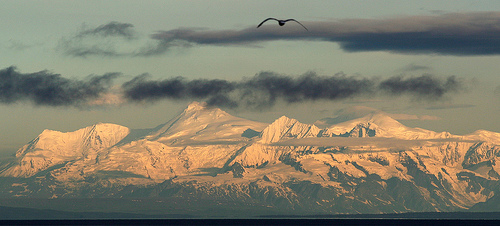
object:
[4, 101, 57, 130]
sky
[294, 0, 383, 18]
sky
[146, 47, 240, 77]
sky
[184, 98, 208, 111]
top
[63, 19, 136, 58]
cloud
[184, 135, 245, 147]
snow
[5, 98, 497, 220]
snow valley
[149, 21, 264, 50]
cloud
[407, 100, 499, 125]
sky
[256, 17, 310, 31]
bird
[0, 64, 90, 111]
black clouds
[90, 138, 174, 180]
moutain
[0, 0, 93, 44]
sky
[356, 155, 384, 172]
snow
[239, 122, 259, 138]
shadow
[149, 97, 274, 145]
mountain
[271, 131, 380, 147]
snow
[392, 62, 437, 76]
clouds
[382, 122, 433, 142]
snow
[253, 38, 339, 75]
sky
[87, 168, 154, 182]
shadow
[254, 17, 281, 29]
wing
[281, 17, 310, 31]
wing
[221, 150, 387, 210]
marks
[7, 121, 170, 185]
light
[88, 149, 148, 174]
snow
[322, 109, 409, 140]
mountain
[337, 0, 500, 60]
background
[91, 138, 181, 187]
mountain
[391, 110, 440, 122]
cloud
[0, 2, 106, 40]
air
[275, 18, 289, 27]
body